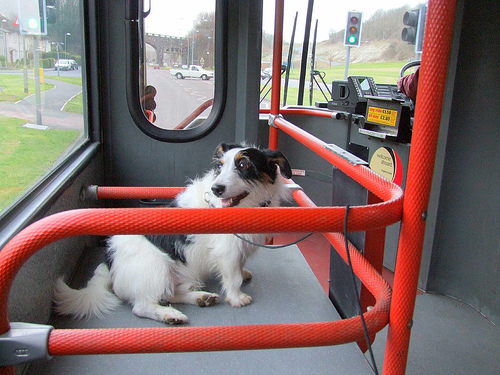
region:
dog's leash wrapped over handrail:
[200, 188, 385, 373]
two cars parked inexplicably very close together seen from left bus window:
[50, 55, 76, 70]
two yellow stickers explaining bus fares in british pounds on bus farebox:
[360, 100, 395, 125]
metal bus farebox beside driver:
[350, 90, 410, 140]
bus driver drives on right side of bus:
[385, 60, 415, 105]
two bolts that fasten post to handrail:
[400, 205, 425, 330]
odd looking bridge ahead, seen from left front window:
[139, 28, 195, 71]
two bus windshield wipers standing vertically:
[260, 7, 331, 107]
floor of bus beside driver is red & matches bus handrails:
[238, 203, 427, 311]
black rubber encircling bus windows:
[0, 0, 235, 255]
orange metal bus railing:
[1, 112, 403, 320]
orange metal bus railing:
[266, 1, 295, 153]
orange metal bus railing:
[371, 7, 469, 371]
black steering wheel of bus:
[398, 59, 422, 84]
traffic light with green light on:
[343, 9, 361, 45]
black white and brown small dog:
[53, 137, 287, 324]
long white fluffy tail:
[55, 260, 134, 316]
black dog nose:
[211, 182, 225, 194]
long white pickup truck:
[169, 66, 211, 81]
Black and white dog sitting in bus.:
[43, 140, 298, 317]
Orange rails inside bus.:
[298, 128, 435, 373]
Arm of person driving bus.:
[397, 64, 422, 101]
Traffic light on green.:
[336, 7, 367, 83]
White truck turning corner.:
[165, 59, 215, 86]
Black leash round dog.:
[338, 203, 383, 372]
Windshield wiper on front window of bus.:
[303, 19, 333, 114]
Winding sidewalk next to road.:
[13, 68, 78, 128]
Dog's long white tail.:
[55, 256, 127, 321]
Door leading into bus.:
[101, 9, 246, 194]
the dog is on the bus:
[54, 140, 291, 324]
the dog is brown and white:
[47, 140, 296, 326]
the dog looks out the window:
[50, 139, 300, 320]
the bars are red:
[1, 2, 449, 368]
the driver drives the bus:
[396, 67, 421, 109]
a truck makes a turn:
[171, 65, 216, 80]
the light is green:
[346, 8, 360, 48]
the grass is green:
[1, 68, 81, 217]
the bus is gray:
[5, 1, 499, 371]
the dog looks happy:
[210, 140, 290, 214]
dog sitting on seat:
[60, 131, 333, 305]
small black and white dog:
[54, 136, 289, 311]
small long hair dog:
[65, 150, 286, 320]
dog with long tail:
[54, 133, 300, 323]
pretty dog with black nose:
[62, 122, 297, 318]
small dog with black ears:
[64, 122, 297, 312]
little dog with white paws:
[52, 115, 296, 312]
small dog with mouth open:
[85, 129, 318, 305]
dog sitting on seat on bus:
[95, 134, 320, 316]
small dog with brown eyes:
[57, 119, 282, 308]